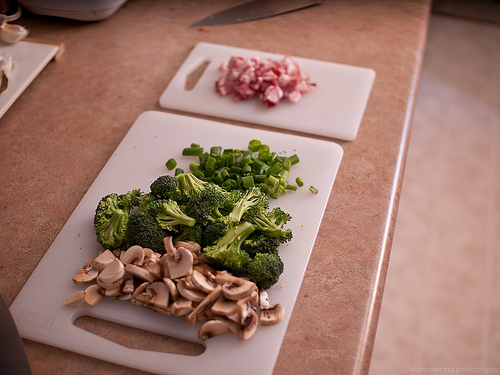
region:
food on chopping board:
[74, 27, 369, 345]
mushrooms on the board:
[39, 233, 301, 349]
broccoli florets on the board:
[72, 161, 302, 283]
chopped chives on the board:
[162, 125, 329, 198]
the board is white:
[81, 115, 343, 272]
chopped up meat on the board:
[176, 33, 339, 108]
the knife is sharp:
[175, 0, 374, 38]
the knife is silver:
[158, 0, 343, 35]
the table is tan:
[2, 60, 171, 225]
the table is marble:
[328, 16, 402, 266]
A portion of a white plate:
[318, 54, 373, 141]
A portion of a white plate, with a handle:
[164, 39, 214, 114]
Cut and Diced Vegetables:
[183, 134, 321, 194]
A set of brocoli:
[221, 195, 295, 275]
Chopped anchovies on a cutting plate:
[198, 281, 285, 343]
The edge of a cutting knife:
[188, 2, 230, 35]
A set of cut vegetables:
[215, 54, 324, 110]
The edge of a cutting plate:
[3, 42, 67, 90]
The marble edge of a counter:
[374, 0, 447, 374]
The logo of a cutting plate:
[11, 307, 65, 332]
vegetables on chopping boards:
[74, 14, 381, 343]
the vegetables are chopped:
[85, 119, 330, 339]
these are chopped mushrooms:
[121, 250, 241, 327]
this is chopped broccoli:
[151, 199, 238, 241]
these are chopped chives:
[178, 126, 267, 175]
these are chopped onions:
[221, 44, 308, 106]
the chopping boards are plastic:
[48, 37, 379, 314]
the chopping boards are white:
[61, 29, 331, 313]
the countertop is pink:
[58, 6, 480, 336]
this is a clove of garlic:
[1, 16, 56, 74]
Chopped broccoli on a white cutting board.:
[7, 111, 346, 373]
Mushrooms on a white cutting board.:
[5, 108, 341, 373]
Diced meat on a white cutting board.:
[155, 36, 375, 136]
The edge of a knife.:
[180, 0, 330, 29]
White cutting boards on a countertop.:
[0, 5, 430, 371]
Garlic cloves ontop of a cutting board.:
[0, 10, 60, 136]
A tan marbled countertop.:
[0, 0, 425, 370]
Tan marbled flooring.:
[365, 80, 495, 370]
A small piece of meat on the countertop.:
[188, 19, 213, 41]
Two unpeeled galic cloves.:
[0, 17, 30, 77]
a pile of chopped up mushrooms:
[72, 247, 282, 342]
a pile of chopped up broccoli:
[79, 175, 288, 274]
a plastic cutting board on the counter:
[15, 112, 348, 374]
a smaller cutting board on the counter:
[153, 43, 373, 136]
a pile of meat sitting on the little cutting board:
[214, 53, 311, 104]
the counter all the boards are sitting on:
[2, 2, 434, 374]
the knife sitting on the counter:
[188, 3, 313, 24]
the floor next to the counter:
[378, 6, 498, 373]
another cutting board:
[4, 35, 68, 110]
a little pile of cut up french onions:
[163, 135, 307, 195]